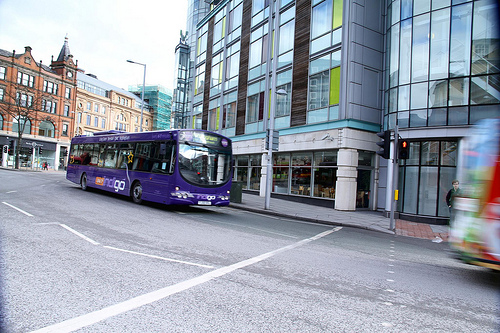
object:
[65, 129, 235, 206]
bus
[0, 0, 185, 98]
sky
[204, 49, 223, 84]
window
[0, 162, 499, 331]
road